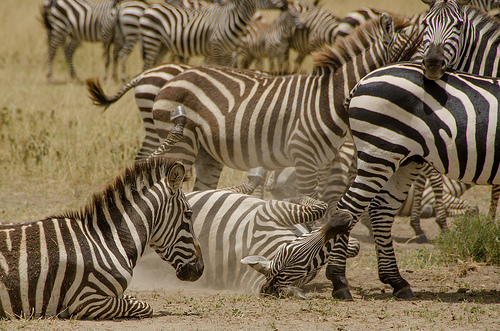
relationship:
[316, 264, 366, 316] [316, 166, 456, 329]
edge of a leg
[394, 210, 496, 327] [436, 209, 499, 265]
part of a grass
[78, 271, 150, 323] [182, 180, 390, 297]
part of a zebra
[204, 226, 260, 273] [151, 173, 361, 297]
back of zebra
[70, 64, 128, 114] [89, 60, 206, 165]
moving tail of zebra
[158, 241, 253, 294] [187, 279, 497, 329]
dust from ground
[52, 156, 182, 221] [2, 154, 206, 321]
mane on zebra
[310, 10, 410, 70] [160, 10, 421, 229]
mane on zebra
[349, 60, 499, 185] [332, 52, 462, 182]
stripes on hindquarter